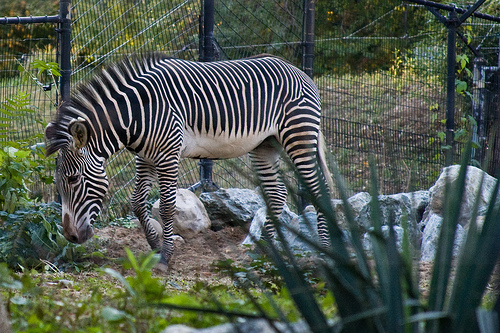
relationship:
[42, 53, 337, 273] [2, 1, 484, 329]
animal in park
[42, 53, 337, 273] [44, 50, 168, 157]
animal has hair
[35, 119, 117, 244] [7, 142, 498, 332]
head down ground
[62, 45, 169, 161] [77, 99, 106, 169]
hair along neck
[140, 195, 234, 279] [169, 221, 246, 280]
boulder on dirt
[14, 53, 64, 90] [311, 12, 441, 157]
chain link fence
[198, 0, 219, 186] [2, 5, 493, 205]
post on fence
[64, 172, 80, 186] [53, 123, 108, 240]
eye on side of face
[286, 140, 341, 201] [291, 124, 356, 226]
hair on tail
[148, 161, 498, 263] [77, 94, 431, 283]
rocks in park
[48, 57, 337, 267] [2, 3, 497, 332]
animal enclosed zoo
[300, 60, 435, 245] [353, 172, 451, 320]
sisal like plant on right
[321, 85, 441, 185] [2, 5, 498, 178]
fencing metallic bars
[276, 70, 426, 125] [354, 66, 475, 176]
day in park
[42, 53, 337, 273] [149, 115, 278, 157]
animal unmarked abdomen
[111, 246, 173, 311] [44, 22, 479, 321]
plants in a park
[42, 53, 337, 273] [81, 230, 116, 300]
animal looking down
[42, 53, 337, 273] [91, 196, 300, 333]
animal in a zoo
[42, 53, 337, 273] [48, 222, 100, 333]
animal sniffing a plant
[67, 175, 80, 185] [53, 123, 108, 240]
eye on face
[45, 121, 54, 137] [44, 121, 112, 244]
ear on zebras head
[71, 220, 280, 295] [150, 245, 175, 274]
dirt beneath hoof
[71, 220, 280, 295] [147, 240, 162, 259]
dirt beneath hoof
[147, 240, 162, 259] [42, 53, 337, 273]
hoof of animal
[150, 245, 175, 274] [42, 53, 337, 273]
hoof of animal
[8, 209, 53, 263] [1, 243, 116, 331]
plant on ground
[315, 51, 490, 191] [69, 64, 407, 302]
fence behind zebra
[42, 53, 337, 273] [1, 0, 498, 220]
animal standing in front of fence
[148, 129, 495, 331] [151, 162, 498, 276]
plant in front of rock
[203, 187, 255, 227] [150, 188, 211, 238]
rock next to boulder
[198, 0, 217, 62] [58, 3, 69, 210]
post right of fence post